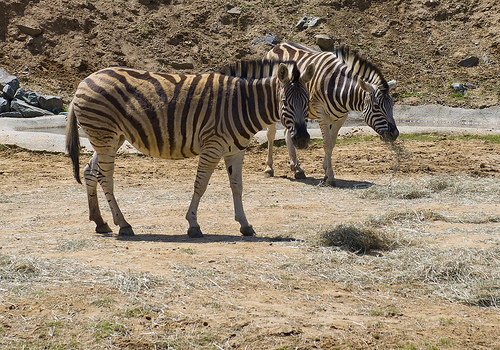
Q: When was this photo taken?
A: During the daytime.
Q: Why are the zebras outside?
A: They are grazing.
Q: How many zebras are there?
A: Two.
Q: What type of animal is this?
A: Zebra.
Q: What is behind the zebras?
A: Dirt.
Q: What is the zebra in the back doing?
A: Eating grass.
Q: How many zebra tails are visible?
A: One.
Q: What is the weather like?
A: Sunny.